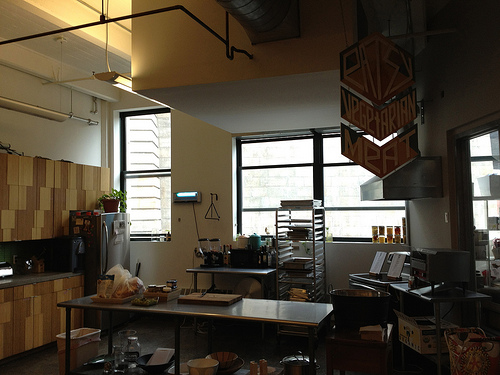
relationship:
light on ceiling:
[90, 5, 169, 110] [0, 1, 144, 103]